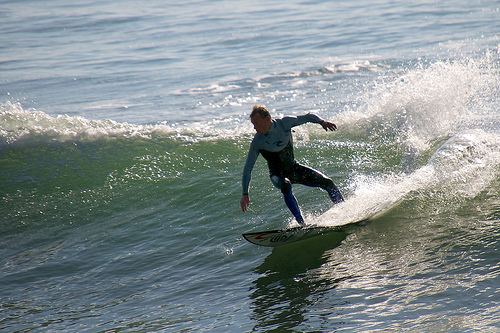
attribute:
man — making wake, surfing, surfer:
[237, 102, 351, 226]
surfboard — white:
[242, 221, 359, 258]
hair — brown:
[248, 107, 275, 124]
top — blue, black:
[239, 112, 322, 185]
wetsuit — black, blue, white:
[239, 110, 352, 221]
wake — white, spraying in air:
[314, 163, 426, 232]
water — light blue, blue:
[3, 3, 499, 332]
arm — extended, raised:
[282, 112, 323, 133]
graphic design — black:
[268, 233, 296, 247]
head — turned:
[249, 107, 271, 138]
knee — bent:
[320, 174, 336, 191]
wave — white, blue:
[5, 95, 500, 248]